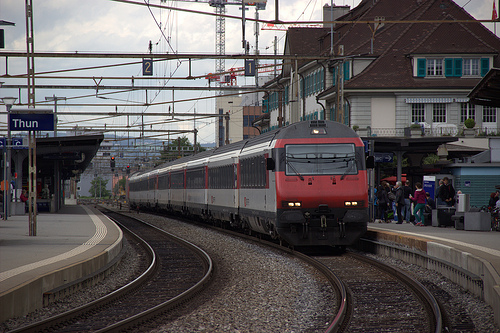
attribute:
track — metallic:
[11, 192, 233, 330]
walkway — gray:
[367, 218, 498, 296]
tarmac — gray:
[2, 189, 122, 295]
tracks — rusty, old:
[3, 205, 443, 331]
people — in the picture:
[369, 172, 459, 229]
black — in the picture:
[286, 229, 354, 244]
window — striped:
[412, 106, 448, 122]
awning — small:
[403, 95, 468, 105]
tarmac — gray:
[0, 201, 123, 299]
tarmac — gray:
[368, 221, 498, 255]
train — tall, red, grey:
[121, 130, 367, 248]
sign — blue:
[4, 110, 61, 130]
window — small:
[424, 55, 444, 77]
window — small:
[460, 57, 481, 77]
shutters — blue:
[413, 56, 427, 77]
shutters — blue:
[442, 55, 464, 80]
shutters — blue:
[479, 55, 491, 78]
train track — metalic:
[22, 203, 458, 330]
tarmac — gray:
[4, 199, 122, 312]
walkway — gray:
[4, 201, 122, 330]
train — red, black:
[101, 134, 377, 252]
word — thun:
[12, 114, 48, 132]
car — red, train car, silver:
[115, 111, 377, 261]